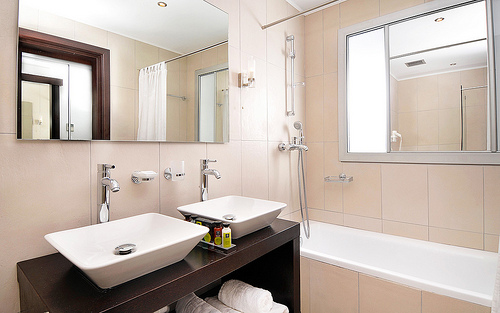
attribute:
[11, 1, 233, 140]
mirror — clear, large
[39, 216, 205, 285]
color — white, clean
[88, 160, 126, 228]
tap — closed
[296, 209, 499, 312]
tub — bath, white, clean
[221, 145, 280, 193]
tile — pink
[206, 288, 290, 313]
towels — rolled up, stacked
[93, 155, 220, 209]
faucets — modern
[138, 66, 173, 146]
shower curtain — white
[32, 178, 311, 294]
sinks — white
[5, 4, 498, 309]
room — bathroom, modern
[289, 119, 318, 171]
shower sprayer — silver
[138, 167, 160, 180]
soap — white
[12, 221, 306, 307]
vanity — brown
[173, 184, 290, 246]
sink — square, white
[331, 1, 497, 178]
mirror — framed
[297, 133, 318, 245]
tubing — metal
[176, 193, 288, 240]
sink — white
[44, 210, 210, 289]
sink — white